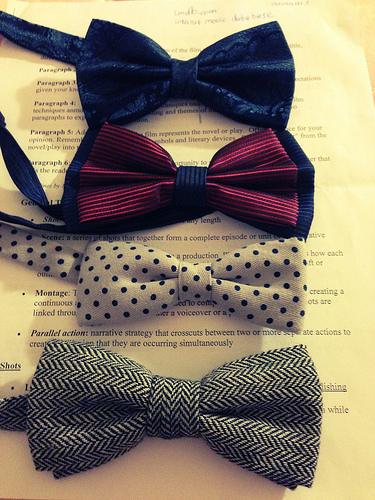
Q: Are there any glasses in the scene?
A: No, there are no glasses.